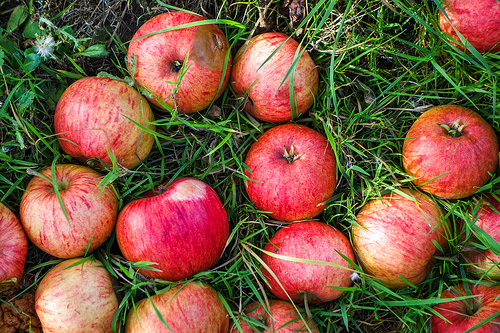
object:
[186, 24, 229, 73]
mark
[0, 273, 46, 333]
dirt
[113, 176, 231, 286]
apple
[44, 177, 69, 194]
apple bottom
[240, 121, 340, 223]
apple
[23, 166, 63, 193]
stem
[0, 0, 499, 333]
ground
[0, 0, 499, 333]
green grass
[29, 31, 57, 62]
spore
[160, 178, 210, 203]
patch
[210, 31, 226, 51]
spot